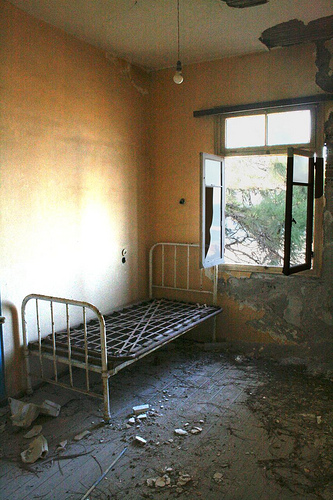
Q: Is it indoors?
A: Yes, it is indoors.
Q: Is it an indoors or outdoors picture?
A: It is indoors.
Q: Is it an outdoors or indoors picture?
A: It is indoors.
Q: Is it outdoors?
A: No, it is indoors.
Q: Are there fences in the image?
A: No, there are no fences.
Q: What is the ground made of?
A: The ground is made of wood.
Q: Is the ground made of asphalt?
A: No, the ground is made of wood.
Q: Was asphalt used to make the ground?
A: No, the ground is made of wood.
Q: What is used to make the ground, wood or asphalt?
A: The ground is made of wood.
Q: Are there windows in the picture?
A: Yes, there is a window.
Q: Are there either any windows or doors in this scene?
A: Yes, there is a window.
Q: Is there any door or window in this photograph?
A: Yes, there is a window.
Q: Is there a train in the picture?
A: No, there are no trains.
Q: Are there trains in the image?
A: No, there are no trains.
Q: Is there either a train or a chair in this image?
A: No, there are no trains or chairs.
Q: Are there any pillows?
A: No, there are no pillows.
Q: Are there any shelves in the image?
A: No, there are no shelves.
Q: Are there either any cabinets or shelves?
A: No, there are no shelves or cabinets.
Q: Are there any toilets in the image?
A: No, there are no toilets.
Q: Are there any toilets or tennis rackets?
A: No, there are no toilets or tennis rackets.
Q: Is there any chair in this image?
A: No, there are no chairs.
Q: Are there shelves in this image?
A: No, there are no shelves.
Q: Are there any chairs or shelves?
A: No, there are no shelves or chairs.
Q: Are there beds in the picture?
A: Yes, there is a bed.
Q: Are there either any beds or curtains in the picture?
A: Yes, there is a bed.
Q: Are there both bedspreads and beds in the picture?
A: No, there is a bed but no bedspreads.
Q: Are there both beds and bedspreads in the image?
A: No, there is a bed but no bedspreads.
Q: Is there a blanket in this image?
A: No, there are no blankets.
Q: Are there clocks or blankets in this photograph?
A: No, there are no blankets or clocks.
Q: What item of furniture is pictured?
A: The piece of furniture is a bed.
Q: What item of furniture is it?
A: The piece of furniture is a bed.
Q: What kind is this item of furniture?
A: This is a bed.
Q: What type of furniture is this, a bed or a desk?
A: This is a bed.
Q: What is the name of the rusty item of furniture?
A: The piece of furniture is a bed.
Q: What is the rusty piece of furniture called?
A: The piece of furniture is a bed.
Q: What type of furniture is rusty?
A: The furniture is a bed.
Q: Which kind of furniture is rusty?
A: The furniture is a bed.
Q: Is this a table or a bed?
A: This is a bed.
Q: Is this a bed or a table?
A: This is a bed.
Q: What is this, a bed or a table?
A: This is a bed.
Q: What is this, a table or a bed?
A: This is a bed.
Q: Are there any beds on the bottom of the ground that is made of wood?
A: Yes, there is a bed on the bottom of the ground.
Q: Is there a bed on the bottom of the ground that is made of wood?
A: Yes, there is a bed on the bottom of the ground.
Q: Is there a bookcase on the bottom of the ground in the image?
A: No, there is a bed on the bottom of the ground.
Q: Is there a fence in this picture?
A: No, there are no fences.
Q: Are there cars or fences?
A: No, there are no fences or cars.